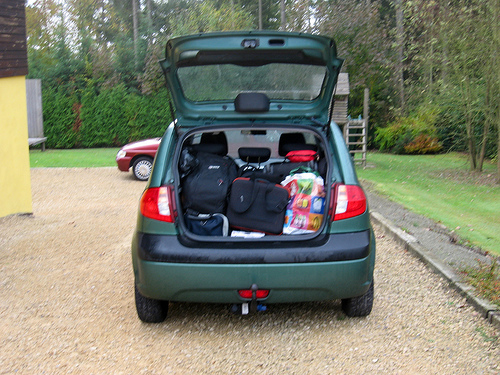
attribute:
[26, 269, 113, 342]
driveway — gravel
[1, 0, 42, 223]
building — yellow 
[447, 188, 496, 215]
area — green, grassy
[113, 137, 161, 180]
car — red 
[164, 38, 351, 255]
trunk — open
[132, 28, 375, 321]
car — green 